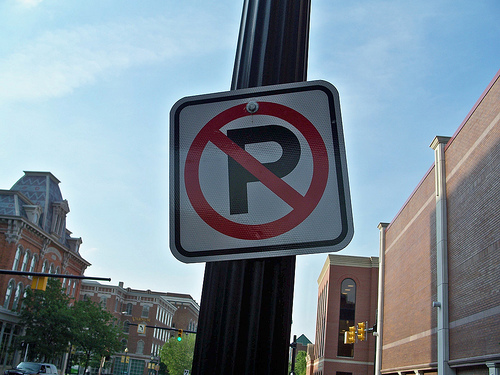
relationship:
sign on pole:
[170, 79, 355, 264] [189, 1, 314, 372]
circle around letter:
[186, 102, 328, 240] [227, 123, 300, 216]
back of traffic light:
[32, 273, 46, 291] [30, 276, 48, 292]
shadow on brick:
[429, 142, 498, 374] [377, 69, 499, 369]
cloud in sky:
[1, 1, 41, 37] [0, 0, 243, 304]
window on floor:
[169, 315, 174, 328] [82, 284, 176, 326]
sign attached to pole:
[170, 79, 355, 264] [189, 1, 314, 372]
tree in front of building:
[295, 350, 309, 374] [314, 255, 379, 374]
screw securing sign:
[247, 100, 259, 114] [170, 79, 355, 264]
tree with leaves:
[295, 350, 309, 374] [295, 348, 308, 374]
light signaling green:
[176, 335, 182, 341] [178, 335, 183, 340]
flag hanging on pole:
[99, 356, 108, 367] [97, 351, 108, 372]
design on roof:
[43, 244, 63, 264] [0, 170, 91, 273]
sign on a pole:
[170, 79, 355, 264] [189, 1, 314, 372]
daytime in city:
[3, 0, 499, 374] [0, 1, 499, 374]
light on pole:
[348, 323, 354, 343] [365, 324, 378, 333]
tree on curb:
[295, 350, 309, 374] [293, 372, 306, 374]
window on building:
[337, 276, 358, 356] [314, 255, 379, 374]